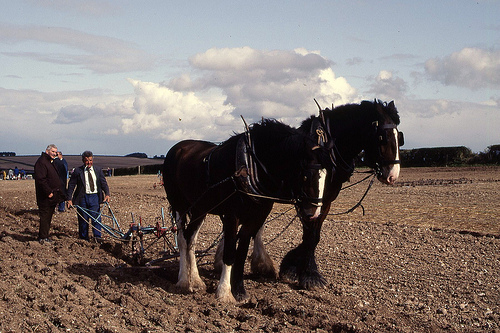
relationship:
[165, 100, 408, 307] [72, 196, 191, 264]
clydesdales at work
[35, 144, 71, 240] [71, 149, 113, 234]
man watching man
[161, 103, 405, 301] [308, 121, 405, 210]
horses with markings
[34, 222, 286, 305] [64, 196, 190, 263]
soil being plowed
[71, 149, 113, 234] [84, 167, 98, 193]
man has tie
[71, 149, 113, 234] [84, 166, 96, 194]
man has shirt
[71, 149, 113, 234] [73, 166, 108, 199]
man has coat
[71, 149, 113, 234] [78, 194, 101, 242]
man has jeans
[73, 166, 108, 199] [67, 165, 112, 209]
coat for suit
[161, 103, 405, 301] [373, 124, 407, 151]
horses have blinders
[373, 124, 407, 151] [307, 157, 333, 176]
blinders for focus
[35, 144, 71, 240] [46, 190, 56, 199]
man with hand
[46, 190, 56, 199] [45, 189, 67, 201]
hand in pocket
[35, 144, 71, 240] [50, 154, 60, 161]
man has beard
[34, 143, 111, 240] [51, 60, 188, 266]
people in background